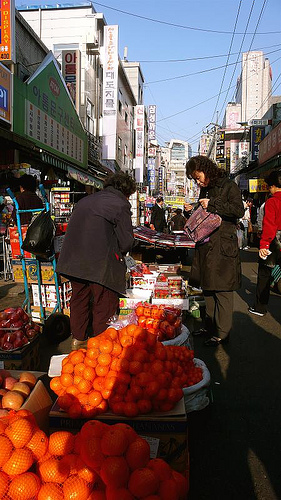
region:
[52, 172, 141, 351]
A woman with brown hair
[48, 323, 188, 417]
A pile of oranges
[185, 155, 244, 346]
A woman in a long coat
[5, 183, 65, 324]
A blue metal cart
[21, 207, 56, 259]
A black plastic bag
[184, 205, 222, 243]
A purple purse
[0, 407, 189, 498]
Mesh bags of oranges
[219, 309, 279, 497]
A person's shaddow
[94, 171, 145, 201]
head of a person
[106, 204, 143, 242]
arm of a person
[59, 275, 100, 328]
leg of a person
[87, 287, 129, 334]
leg of a person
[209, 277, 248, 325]
leg of a person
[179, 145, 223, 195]
head of a person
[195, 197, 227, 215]
hand of a person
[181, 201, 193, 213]
hand of a person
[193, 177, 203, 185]
nose of a person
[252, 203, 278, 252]
arm of a person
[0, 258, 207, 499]
Lots of oranges for sale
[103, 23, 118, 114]
A sign in not english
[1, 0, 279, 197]
Many signs on the buildings advertising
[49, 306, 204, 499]
Shadows cast on the oranges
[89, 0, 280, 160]
Wires criss crossing above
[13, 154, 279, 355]
People shopping for food at the market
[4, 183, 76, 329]
A hand truck with boxes on it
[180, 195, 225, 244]
Lady holding onto her purse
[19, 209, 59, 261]
Black bag on the hand truck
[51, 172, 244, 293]
Both women are wearing coats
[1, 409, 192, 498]
a bundle of oranges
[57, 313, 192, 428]
a bundle of oranges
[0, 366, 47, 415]
a box of red apples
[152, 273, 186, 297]
a box of red strawberries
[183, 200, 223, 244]
a purple purse in a woman's hands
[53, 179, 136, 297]
a blue jacket on a woman's back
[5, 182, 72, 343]
a blue hand dolly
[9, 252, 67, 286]
a box of bananas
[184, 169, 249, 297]
a black trench coat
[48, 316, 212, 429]
Oranges on the table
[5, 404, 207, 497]
The oranges are in the bags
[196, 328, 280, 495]
Shadows on the ground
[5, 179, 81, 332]
This is a blue carrier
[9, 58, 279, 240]
This is not America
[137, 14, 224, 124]
Light blue is the color of the sky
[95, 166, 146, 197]
The hair is short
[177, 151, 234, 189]
The hair is shoulder length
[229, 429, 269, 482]
This is the street